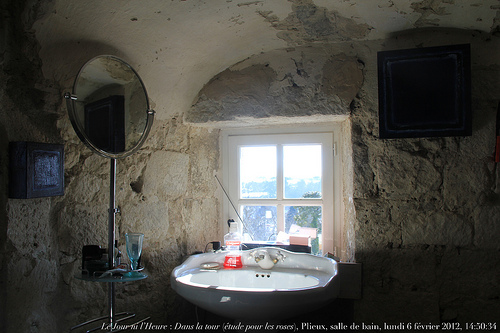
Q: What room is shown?
A: Bathroom.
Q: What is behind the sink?
A: Window.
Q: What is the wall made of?
A: Rock.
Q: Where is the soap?
A: On the sink.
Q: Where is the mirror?
A: Left side of the sink.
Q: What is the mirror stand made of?
A: Metal.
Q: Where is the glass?
A: On the mirror stand.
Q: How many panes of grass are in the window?
A: 4.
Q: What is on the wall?
A: Window.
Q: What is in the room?
A: A mirror.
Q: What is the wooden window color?
A: White.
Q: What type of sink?
A: Ceramic pedestal.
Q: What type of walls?
A: Cement and stone.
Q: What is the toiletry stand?
A: Silver.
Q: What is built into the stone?
A: Window.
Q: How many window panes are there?
A: 4.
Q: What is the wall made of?
A: Stone.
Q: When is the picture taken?
A: Daytime.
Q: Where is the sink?
A: In front of the window.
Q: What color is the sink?
A: White.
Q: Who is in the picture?
A: No one.